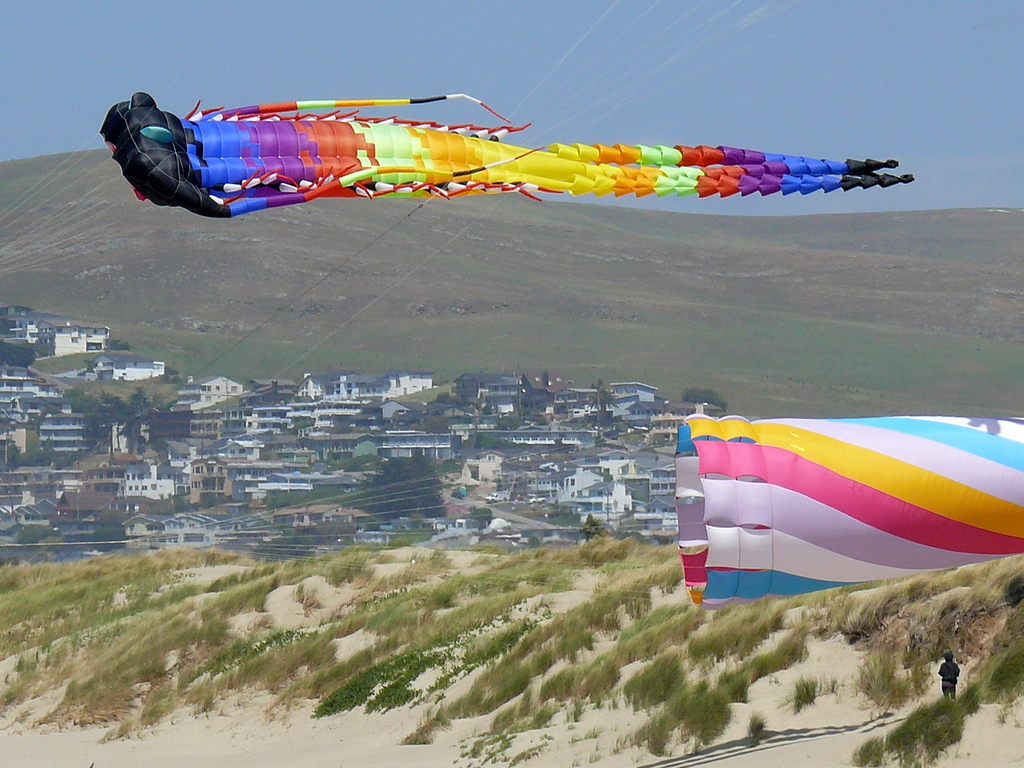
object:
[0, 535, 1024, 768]
grass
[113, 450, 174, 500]
house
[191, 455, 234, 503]
house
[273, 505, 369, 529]
house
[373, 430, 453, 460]
house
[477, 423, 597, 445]
house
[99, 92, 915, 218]
wind sock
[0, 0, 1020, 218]
sky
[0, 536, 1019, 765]
hill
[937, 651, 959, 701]
man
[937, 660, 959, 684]
shirt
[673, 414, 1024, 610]
windsock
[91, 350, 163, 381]
house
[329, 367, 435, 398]
house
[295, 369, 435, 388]
roof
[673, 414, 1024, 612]
balloon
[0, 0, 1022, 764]
air